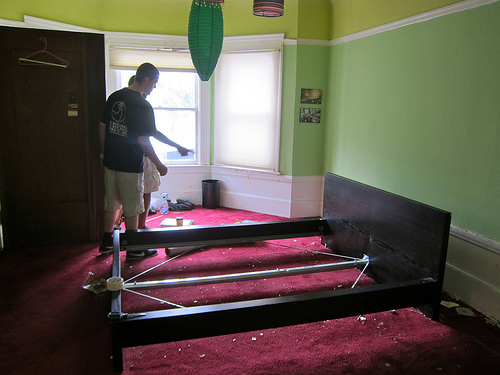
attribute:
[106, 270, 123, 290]
tape — rolled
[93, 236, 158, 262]
shoes — black, nike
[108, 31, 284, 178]
window — bay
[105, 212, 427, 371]
frame — dark wood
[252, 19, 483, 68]
molding — white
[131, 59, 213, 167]
bay window — eclectic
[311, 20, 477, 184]
wall — yellow green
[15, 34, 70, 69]
hanger — empty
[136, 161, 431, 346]
carpet — red, shag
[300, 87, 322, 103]
picture — small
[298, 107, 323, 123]
picture — small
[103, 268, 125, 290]
tape — clear, rolled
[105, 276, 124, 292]
tape — clear